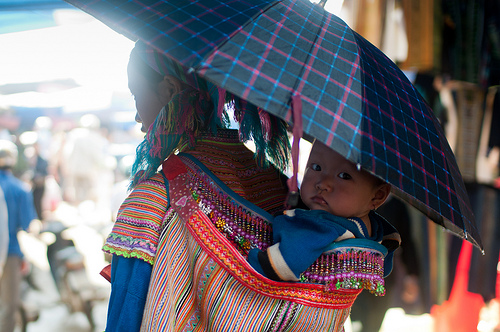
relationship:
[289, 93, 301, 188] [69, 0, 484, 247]
ribbon on umbrella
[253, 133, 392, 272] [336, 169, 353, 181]
baby has eye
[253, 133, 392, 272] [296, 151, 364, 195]
baby has eyes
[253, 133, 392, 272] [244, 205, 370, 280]
baby has outfit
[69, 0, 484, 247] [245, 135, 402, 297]
umbrella above kid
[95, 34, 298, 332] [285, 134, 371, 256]
lady carrying kid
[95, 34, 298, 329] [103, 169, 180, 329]
lady has left arm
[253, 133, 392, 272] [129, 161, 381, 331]
baby in carrier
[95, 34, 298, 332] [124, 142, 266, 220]
lady wearing shirt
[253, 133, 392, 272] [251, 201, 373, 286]
baby wearing outfit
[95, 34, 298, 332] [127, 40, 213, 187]
lady wearing bandana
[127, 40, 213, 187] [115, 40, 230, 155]
bandana on head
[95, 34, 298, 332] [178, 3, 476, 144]
lady under umbrella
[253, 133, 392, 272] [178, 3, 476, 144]
baby under umbrella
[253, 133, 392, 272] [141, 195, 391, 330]
baby in pouch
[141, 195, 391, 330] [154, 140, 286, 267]
pouch on back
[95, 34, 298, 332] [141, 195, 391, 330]
lady wearing pouch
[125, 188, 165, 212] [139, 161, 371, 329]
stripes are on pouch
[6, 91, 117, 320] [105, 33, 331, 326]
people moving ahead of mother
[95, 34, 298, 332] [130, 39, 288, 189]
lady wearing scarf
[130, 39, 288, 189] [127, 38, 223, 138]
scarf on head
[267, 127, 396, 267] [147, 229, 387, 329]
baby inside bag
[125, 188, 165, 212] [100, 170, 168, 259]
stripes are on sleeve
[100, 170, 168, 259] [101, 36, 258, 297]
sleeve on woman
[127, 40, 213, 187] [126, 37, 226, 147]
bandana hanging on head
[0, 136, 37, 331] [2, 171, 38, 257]
person wearing shirt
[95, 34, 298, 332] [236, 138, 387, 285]
lady carrying child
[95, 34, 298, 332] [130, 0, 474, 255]
lady under umbrella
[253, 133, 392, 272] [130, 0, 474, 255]
baby under umbrella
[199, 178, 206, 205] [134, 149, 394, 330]
rows hanging along pouch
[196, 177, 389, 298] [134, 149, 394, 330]
rows hanging along pouch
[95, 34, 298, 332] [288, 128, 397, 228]
lady behind baby